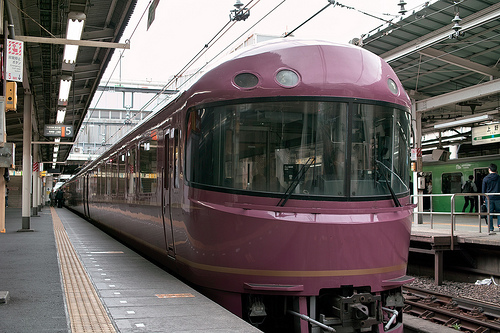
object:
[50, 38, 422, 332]
train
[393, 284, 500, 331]
tracks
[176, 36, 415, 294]
front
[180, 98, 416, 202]
windshield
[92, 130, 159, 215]
windows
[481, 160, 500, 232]
man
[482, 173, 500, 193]
blue shirt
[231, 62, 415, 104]
headlights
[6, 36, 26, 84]
sign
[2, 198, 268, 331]
unloading platform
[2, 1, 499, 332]
train station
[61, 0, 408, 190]
power lines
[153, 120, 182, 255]
door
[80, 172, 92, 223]
door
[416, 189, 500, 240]
guardrail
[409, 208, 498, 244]
platform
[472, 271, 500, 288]
trash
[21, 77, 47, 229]
steel beams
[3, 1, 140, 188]
canopy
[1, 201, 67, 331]
pavement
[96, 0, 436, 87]
sky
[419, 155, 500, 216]
building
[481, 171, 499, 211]
jacket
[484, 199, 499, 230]
pants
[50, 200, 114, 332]
barrier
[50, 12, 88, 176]
lights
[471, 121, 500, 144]
sign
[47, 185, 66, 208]
passengers